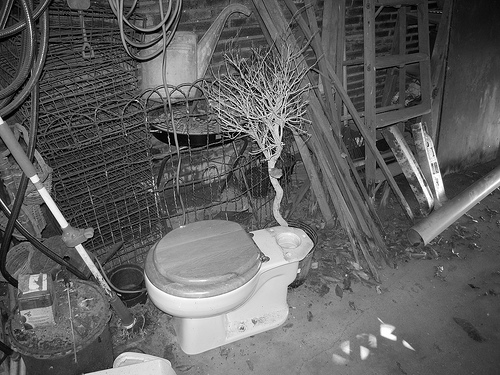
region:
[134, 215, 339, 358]
toilet with a wooden lid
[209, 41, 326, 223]
small tree without leaves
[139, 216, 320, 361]
discarded white toilet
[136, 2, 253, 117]
outside watering can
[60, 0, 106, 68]
small hanging shovel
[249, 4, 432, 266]
pile of thin wooden posts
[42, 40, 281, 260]
pile of metal fencing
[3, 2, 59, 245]
garden hose hanging on the wall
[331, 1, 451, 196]
metal ladder leaning against a wall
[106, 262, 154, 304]
small black plant pot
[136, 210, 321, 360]
toilet abandoned in an alley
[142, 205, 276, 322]
abandoned toilet has a very nice woodgrain lid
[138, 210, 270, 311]
this toilet lid is worth salvaging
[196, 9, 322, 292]
a poor sad potted tree abandoned in an alley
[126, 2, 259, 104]
a watering can in the alley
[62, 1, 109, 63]
this little shovel needs a little bucket to go with it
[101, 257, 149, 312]
empty pot for potted plants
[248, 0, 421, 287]
a stack of posts to help baby trees to stand upright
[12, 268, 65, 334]
this looks like a box of grass fertilizer or something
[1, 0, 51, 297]
kind of coiled hose in the alley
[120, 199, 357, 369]
an old toilet seat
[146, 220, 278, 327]
a wooden lid on toilet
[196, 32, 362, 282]
a tree in a pot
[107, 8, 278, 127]
a watering can above toilet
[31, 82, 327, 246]
fencing against the wall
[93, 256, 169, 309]
an empty black pot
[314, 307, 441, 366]
sunlight on the floor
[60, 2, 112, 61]
a small hanging shovel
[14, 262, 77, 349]
a box on a bucket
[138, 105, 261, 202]
an old black grill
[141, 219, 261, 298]
wooden toilet seat and lid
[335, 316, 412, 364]
sunlight on the ground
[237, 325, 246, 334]
bolt hole on the toilet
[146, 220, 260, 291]
the lid is closed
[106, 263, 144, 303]
empty black bucket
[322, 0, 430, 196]
ladder leaning against the wall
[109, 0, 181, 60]
loops of a cord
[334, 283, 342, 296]
leaf on the ground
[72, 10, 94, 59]
a shovel handle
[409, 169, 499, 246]
a pipe on the ground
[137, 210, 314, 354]
Broken toilet sitting outdoors.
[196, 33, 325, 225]
Dead tree outdoors next to wire fence.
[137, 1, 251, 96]
Old watering can covered in dirt.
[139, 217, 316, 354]
Wooden toilet seat on a broken toilet.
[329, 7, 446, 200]
Wooden ladder leaning on brick wall.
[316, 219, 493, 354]
Dry leaves scattered on dirty floor.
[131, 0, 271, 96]
Brick wall behind watering can.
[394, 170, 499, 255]
Pipe sitting on dirty floor.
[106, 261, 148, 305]
Black plastic flower pot.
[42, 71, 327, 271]
Wire fence behind broken toilet.